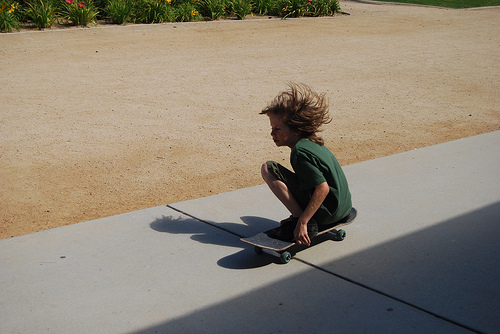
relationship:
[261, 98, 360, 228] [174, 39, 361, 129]
boy with hair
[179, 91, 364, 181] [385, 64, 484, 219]
boy's hair in air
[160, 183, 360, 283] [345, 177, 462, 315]
boy's shadow on sidewalk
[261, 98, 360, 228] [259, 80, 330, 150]
boy with hair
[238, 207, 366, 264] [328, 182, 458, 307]
skateboard on pavement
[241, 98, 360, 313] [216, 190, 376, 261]
boy sitting skateboard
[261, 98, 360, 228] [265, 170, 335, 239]
boy wearing shorts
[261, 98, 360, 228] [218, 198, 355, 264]
boy on a skateboard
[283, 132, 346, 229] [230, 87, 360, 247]
shirt on a boy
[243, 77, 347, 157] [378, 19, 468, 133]
hair in wind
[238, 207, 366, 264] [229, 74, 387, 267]
skateboard under boy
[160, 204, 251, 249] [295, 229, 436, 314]
boy's shadow by line